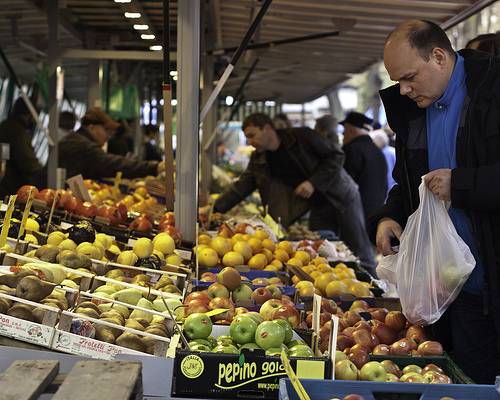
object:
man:
[366, 17, 499, 386]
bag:
[375, 174, 477, 326]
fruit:
[394, 261, 466, 327]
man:
[213, 112, 379, 280]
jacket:
[214, 126, 360, 228]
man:
[35, 108, 175, 193]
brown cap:
[85, 107, 121, 130]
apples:
[185, 266, 454, 384]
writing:
[171, 351, 333, 399]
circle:
[180, 355, 204, 379]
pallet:
[1, 359, 144, 399]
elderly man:
[341, 134, 389, 217]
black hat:
[338, 111, 373, 131]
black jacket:
[342, 134, 389, 218]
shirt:
[425, 50, 487, 296]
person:
[0, 96, 48, 200]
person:
[141, 124, 162, 162]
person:
[107, 117, 134, 153]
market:
[0, 0, 500, 400]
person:
[338, 111, 388, 217]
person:
[315, 115, 340, 143]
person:
[273, 113, 291, 129]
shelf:
[0, 268, 177, 361]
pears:
[0, 267, 182, 362]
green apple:
[230, 315, 255, 343]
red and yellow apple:
[183, 266, 387, 382]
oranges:
[196, 229, 374, 298]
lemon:
[23, 218, 182, 273]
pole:
[176, 1, 199, 245]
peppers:
[17, 185, 182, 247]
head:
[383, 19, 454, 108]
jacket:
[36, 127, 159, 190]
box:
[0, 176, 196, 398]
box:
[175, 229, 500, 399]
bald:
[387, 19, 431, 40]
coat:
[365, 33, 499, 315]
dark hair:
[407, 19, 455, 62]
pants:
[428, 290, 500, 387]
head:
[81, 107, 121, 146]